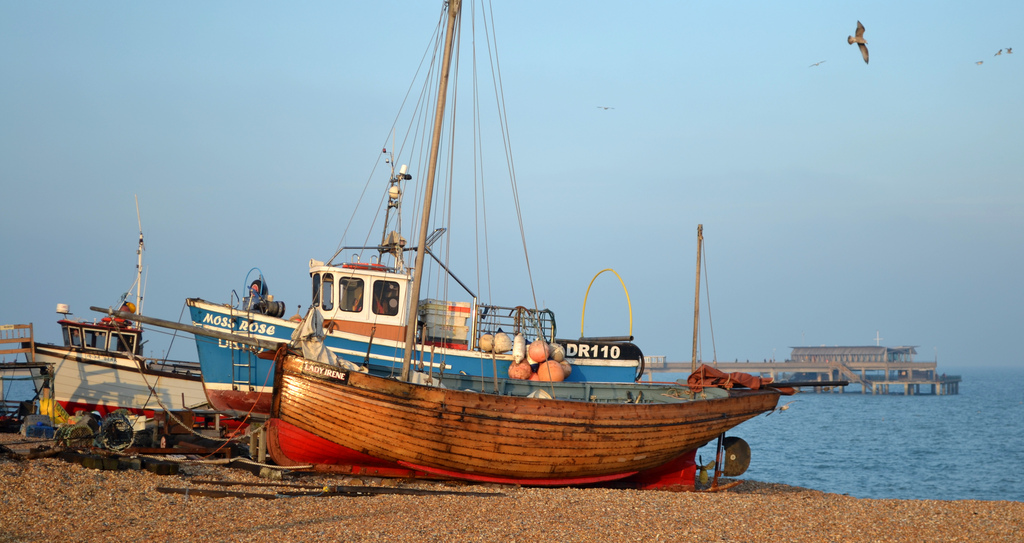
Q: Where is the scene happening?
A: On a beach.